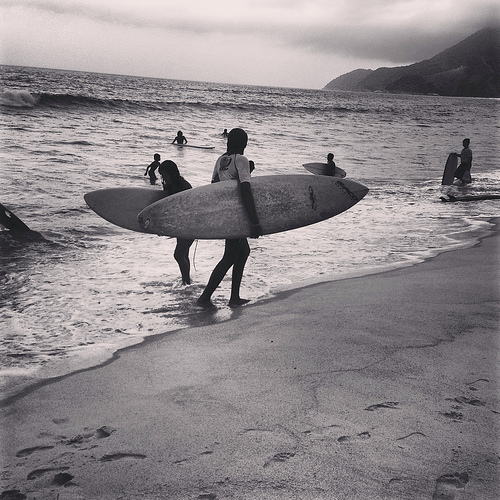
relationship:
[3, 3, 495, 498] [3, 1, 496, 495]
scene  outside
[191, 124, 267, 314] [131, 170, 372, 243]
person carrying surfboard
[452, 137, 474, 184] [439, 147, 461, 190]
man holding surfboard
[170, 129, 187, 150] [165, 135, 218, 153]
man ready to mount surfboard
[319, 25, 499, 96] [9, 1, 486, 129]
mountain are in background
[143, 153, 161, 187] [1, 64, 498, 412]
child walking on surf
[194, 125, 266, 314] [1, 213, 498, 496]
person walking along beach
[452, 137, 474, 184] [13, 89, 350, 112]
man watching wave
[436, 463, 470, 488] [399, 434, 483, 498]
footprint in sand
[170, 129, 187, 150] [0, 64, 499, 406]
man in ocean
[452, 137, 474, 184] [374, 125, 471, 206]
man standing in water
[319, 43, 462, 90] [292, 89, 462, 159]
mountain near water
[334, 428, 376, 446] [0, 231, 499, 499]
footprint in beach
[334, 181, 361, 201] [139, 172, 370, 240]
writing on surfboard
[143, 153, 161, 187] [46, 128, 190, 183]
child in water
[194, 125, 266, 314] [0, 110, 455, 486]
person on beach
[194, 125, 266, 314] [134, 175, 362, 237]
person holding surfboard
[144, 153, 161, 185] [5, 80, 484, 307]
child playing in ocean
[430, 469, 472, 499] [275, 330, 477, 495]
footprint in sand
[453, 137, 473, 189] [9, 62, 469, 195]
man walking into ocean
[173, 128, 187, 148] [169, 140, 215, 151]
man climbing onto surfboard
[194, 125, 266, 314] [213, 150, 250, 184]
person wearing swim shirt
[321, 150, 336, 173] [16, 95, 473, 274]
man walking into ocean